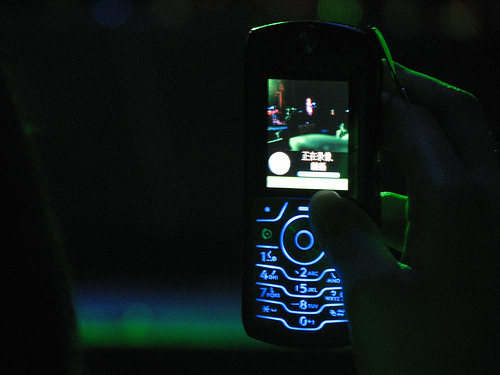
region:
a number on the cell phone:
[257, 285, 279, 299]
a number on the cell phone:
[296, 298, 316, 313]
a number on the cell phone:
[300, 313, 309, 330]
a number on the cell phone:
[257, 267, 272, 280]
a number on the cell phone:
[296, 280, 313, 293]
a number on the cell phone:
[296, 264, 308, 278]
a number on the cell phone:
[260, 250, 275, 262]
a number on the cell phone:
[339, 289, 343, 301]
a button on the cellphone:
[260, 303, 276, 320]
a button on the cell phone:
[329, 307, 344, 321]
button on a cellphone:
[251, 244, 283, 271]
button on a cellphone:
[254, 260, 284, 290]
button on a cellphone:
[260, 278, 283, 301]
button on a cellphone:
[297, 252, 324, 290]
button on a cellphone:
[294, 273, 316, 294]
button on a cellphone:
[326, 268, 346, 288]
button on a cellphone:
[327, 280, 348, 300]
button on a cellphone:
[324, 301, 350, 323]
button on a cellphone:
[294, 313, 321, 335]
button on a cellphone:
[295, 293, 315, 314]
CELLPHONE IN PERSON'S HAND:
[238, 22, 383, 367]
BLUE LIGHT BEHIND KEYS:
[271, 207, 343, 330]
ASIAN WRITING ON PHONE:
[299, 143, 339, 161]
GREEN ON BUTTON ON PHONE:
[259, 220, 280, 244]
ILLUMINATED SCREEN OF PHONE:
[268, 74, 345, 189]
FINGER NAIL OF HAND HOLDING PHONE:
[313, 193, 331, 220]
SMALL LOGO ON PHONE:
[299, 34, 321, 51]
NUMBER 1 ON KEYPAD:
[259, 249, 269, 266]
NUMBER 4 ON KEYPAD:
[259, 267, 268, 283]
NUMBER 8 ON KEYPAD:
[299, 299, 304, 308]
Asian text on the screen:
[297, 150, 332, 161]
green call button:
[255, 222, 278, 246]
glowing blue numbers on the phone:
[256, 250, 343, 330]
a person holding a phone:
[248, 21, 494, 371]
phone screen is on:
[263, 76, 352, 193]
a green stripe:
[74, 319, 249, 348]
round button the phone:
[280, 215, 324, 264]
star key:
[260, 303, 277, 316]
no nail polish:
[308, 190, 351, 230]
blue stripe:
[77, 296, 239, 316]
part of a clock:
[291, 277, 307, 308]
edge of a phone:
[277, 295, 281, 302]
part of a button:
[306, 287, 310, 295]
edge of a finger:
[361, 289, 365, 311]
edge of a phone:
[384, 115, 388, 120]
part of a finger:
[345, 255, 350, 274]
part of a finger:
[322, 215, 326, 218]